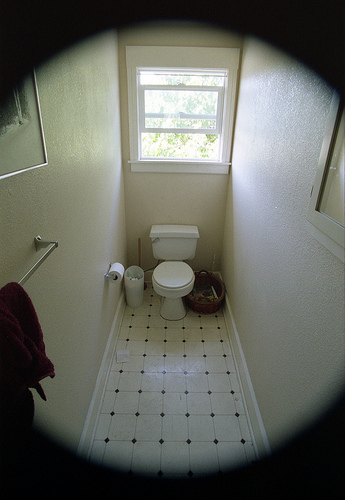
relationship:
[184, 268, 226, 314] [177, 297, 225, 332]
basket on floor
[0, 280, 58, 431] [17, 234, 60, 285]
towel on rack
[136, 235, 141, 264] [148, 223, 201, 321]
handle on toilet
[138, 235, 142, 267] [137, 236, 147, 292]
handle on toilet plunger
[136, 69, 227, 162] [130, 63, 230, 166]
window on frame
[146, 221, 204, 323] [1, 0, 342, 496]
toilet in bathroom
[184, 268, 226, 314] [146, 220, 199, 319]
basket in toilet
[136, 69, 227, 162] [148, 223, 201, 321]
window in toilet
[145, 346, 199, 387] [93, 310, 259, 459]
diamonds on tile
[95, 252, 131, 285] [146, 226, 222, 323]
tissue next to toilet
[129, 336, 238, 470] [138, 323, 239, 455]
tile on floor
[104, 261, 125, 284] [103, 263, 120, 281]
tissue on holder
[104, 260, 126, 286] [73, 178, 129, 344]
holder on wall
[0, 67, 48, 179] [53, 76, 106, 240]
picture on wall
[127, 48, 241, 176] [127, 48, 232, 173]
trimming around window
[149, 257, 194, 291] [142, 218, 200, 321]
lid down on stool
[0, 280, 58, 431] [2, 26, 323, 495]
towel in bathroom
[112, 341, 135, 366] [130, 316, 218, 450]
tissue on floor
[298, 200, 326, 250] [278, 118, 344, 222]
corner of cabinet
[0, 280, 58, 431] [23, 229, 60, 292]
towel hanging from bar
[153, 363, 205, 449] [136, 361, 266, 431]
design on tiles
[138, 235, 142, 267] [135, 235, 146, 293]
handle of toilet plunger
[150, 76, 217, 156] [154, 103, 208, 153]
vegetation in sun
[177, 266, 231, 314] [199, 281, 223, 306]
basket for magazines